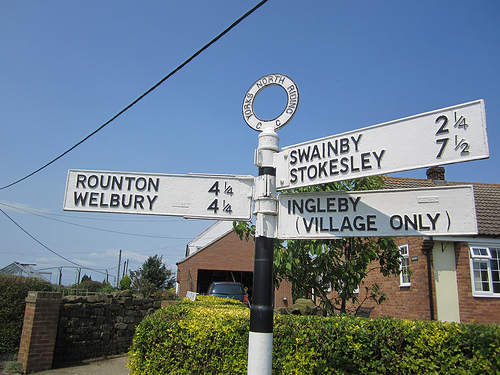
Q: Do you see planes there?
A: No, there are no planes.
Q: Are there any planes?
A: No, there are no planes.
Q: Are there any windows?
A: Yes, there is a window.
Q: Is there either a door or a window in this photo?
A: Yes, there is a window.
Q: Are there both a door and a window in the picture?
A: Yes, there are both a window and a door.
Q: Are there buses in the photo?
A: No, there are no buses.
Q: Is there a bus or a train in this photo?
A: No, there are no buses or trains.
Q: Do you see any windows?
A: Yes, there is a window.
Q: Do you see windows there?
A: Yes, there is a window.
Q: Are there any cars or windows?
A: Yes, there is a window.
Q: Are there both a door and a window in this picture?
A: Yes, there are both a window and a door.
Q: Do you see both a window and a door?
A: Yes, there are both a window and a door.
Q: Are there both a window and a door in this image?
A: Yes, there are both a window and a door.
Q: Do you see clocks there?
A: No, there are no clocks.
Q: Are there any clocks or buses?
A: No, there are no clocks or buses.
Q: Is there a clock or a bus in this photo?
A: No, there are no clocks or buses.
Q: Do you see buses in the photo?
A: No, there are no buses.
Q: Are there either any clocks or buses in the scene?
A: No, there are no buses or clocks.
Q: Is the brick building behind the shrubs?
A: Yes, the building is behind the shrubs.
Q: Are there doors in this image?
A: Yes, there is a door.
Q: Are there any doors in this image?
A: Yes, there is a door.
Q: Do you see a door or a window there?
A: Yes, there is a door.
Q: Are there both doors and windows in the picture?
A: Yes, there are both a door and a window.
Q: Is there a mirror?
A: No, there are no mirrors.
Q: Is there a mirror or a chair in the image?
A: No, there are no mirrors or chairs.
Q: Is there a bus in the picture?
A: No, there are no buses.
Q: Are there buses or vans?
A: No, there are no buses or vans.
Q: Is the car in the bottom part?
A: Yes, the car is in the bottom of the image.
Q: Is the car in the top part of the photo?
A: No, the car is in the bottom of the image.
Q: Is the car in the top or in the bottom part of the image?
A: The car is in the bottom of the image.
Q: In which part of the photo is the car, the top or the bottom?
A: The car is in the bottom of the image.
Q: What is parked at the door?
A: The car is parked at the door.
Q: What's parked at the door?
A: The car is parked at the door.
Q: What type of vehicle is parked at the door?
A: The vehicle is a car.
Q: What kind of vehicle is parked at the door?
A: The vehicle is a car.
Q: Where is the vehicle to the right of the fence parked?
A: The car is parked at the door.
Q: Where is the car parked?
A: The car is parked at the door.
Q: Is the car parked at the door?
A: Yes, the car is parked at the door.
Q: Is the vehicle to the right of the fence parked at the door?
A: Yes, the car is parked at the door.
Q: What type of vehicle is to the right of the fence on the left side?
A: The vehicle is a car.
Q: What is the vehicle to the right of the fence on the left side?
A: The vehicle is a car.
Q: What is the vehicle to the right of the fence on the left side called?
A: The vehicle is a car.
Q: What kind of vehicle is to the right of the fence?
A: The vehicle is a car.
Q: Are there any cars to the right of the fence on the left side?
A: Yes, there is a car to the right of the fence.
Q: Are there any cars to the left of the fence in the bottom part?
A: No, the car is to the right of the fence.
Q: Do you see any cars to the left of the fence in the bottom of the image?
A: No, the car is to the right of the fence.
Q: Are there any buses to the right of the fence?
A: No, there is a car to the right of the fence.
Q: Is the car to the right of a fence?
A: Yes, the car is to the right of a fence.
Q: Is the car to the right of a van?
A: No, the car is to the right of a fence.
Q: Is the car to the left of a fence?
A: No, the car is to the right of a fence.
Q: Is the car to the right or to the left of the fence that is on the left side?
A: The car is to the right of the fence.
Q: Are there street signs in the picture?
A: Yes, there is a street sign.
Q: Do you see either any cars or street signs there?
A: Yes, there is a street sign.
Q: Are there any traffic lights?
A: No, there are no traffic lights.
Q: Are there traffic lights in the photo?
A: No, there are no traffic lights.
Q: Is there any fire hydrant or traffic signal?
A: No, there are no traffic lights or fire hydrants.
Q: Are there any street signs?
A: Yes, there is a street sign.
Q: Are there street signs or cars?
A: Yes, there is a street sign.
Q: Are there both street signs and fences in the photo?
A: Yes, there are both a street sign and a fence.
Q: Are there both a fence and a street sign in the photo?
A: Yes, there are both a street sign and a fence.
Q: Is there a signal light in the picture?
A: No, there are no traffic lights.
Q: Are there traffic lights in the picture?
A: No, there are no traffic lights.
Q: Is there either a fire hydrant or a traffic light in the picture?
A: No, there are no traffic lights or fire hydrants.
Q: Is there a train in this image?
A: No, there are no trains.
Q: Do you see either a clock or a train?
A: No, there are no trains or clocks.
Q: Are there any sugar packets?
A: No, there are no sugar packets.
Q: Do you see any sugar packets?
A: No, there are no sugar packets.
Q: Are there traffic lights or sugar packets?
A: No, there are no sugar packets or traffic lights.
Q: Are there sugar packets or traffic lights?
A: No, there are no sugar packets or traffic lights.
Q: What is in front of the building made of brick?
A: The bushes are in front of the building.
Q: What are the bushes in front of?
A: The bushes are in front of the building.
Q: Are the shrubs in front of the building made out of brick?
A: Yes, the shrubs are in front of the building.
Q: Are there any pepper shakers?
A: No, there are no pepper shakers.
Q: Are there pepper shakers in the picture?
A: No, there are no pepper shakers.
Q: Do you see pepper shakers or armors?
A: No, there are no pepper shakers or armors.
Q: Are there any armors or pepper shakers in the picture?
A: No, there are no pepper shakers or armors.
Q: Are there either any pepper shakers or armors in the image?
A: No, there are no pepper shakers or armors.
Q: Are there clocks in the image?
A: No, there are no clocks.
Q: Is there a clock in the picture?
A: No, there are no clocks.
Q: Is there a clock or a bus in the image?
A: No, there are no clocks or buses.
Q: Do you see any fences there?
A: Yes, there is a fence.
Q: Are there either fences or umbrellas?
A: Yes, there is a fence.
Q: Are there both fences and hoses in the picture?
A: No, there is a fence but no hoses.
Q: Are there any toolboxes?
A: No, there are no toolboxes.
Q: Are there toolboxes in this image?
A: No, there are no toolboxes.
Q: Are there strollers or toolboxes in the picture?
A: No, there are no toolboxes or strollers.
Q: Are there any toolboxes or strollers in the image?
A: No, there are no toolboxes or strollers.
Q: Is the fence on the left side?
A: Yes, the fence is on the left of the image.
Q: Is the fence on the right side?
A: No, the fence is on the left of the image.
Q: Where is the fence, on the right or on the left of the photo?
A: The fence is on the left of the image.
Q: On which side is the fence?
A: The fence is on the left of the image.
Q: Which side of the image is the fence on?
A: The fence is on the left of the image.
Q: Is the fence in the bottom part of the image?
A: Yes, the fence is in the bottom of the image.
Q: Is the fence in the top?
A: No, the fence is in the bottom of the image.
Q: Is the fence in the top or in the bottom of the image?
A: The fence is in the bottom of the image.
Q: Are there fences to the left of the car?
A: Yes, there is a fence to the left of the car.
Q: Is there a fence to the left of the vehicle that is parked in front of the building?
A: Yes, there is a fence to the left of the car.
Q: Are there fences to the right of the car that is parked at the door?
A: No, the fence is to the left of the car.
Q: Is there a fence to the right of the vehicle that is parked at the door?
A: No, the fence is to the left of the car.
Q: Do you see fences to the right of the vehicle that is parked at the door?
A: No, the fence is to the left of the car.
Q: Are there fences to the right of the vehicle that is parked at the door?
A: No, the fence is to the left of the car.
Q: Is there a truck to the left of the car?
A: No, there is a fence to the left of the car.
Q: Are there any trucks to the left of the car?
A: No, there is a fence to the left of the car.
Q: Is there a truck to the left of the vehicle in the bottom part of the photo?
A: No, there is a fence to the left of the car.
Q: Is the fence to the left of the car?
A: Yes, the fence is to the left of the car.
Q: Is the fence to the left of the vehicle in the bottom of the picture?
A: Yes, the fence is to the left of the car.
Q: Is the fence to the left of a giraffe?
A: No, the fence is to the left of the car.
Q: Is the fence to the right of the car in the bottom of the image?
A: No, the fence is to the left of the car.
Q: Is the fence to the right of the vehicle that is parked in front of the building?
A: No, the fence is to the left of the car.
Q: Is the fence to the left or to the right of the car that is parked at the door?
A: The fence is to the left of the car.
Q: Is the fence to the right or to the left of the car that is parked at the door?
A: The fence is to the left of the car.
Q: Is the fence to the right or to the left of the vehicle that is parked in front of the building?
A: The fence is to the left of the car.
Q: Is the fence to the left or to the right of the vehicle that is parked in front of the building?
A: The fence is to the left of the car.